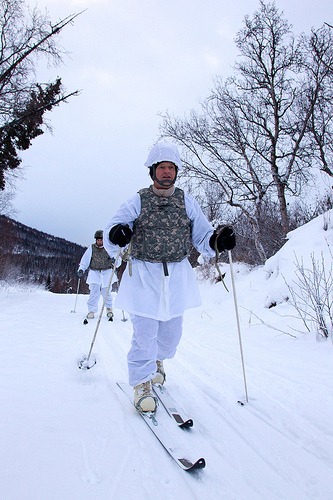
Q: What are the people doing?
A: Skiing.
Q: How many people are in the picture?
A: Two.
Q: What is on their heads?
A: Helmets.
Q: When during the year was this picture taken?
A: Winter.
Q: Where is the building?
A: Behind the men.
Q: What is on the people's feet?
A: Skis.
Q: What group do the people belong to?
A: Military.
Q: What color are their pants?
A: White.